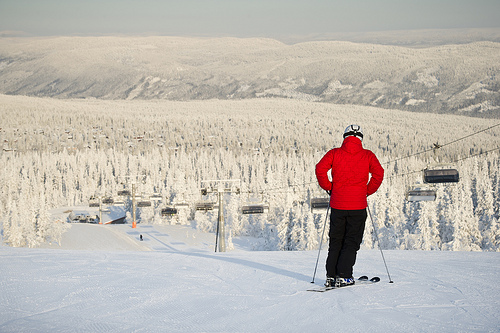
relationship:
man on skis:
[315, 124, 384, 287] [312, 265, 394, 302]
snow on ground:
[25, 251, 494, 332] [4, 210, 485, 329]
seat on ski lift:
[423, 170, 460, 182] [92, 125, 499, 217]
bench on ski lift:
[421, 168, 460, 183] [103, 166, 491, 251]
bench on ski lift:
[405, 188, 437, 202] [103, 166, 491, 251]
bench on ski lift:
[310, 198, 329, 208] [103, 166, 491, 251]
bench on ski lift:
[242, 205, 263, 213] [103, 166, 491, 251]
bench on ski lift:
[161, 207, 177, 217] [103, 166, 491, 251]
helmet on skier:
[340, 121, 366, 138] [302, 112, 404, 297]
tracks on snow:
[5, 272, 162, 331] [2, 219, 481, 329]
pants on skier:
[326, 206, 368, 277] [317, 124, 384, 286]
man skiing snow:
[315, 124, 384, 287] [8, 48, 496, 328]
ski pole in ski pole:
[362, 195, 399, 286] [308, 199, 330, 286]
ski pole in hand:
[362, 195, 399, 286] [325, 179, 335, 194]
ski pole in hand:
[362, 195, 399, 286] [362, 182, 370, 197]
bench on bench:
[423, 167, 460, 182] [240, 203, 262, 213]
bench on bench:
[423, 167, 460, 182] [308, 196, 330, 208]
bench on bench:
[423, 167, 460, 182] [405, 188, 437, 200]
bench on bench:
[423, 167, 460, 182] [160, 206, 177, 215]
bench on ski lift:
[423, 167, 460, 182] [67, 124, 499, 251]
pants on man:
[326, 206, 368, 277] [315, 124, 384, 287]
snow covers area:
[8, 48, 496, 328] [2, 32, 480, 331]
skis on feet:
[306, 276, 380, 292] [325, 272, 350, 287]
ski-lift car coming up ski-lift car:
[310, 196, 330, 207] [241, 203, 265, 213]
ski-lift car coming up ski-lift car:
[310, 196, 330, 207] [194, 201, 212, 211]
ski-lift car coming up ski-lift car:
[310, 196, 330, 207] [159, 206, 176, 216]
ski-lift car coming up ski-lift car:
[310, 196, 330, 207] [422, 165, 459, 182]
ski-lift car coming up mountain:
[310, 196, 330, 207] [5, 241, 475, 328]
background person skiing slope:
[140, 235, 144, 242] [108, 222, 288, 286]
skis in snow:
[308, 275, 378, 292] [8, 48, 496, 328]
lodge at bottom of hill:
[66, 210, 100, 224] [3, 202, 485, 329]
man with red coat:
[315, 124, 384, 287] [312, 134, 385, 214]